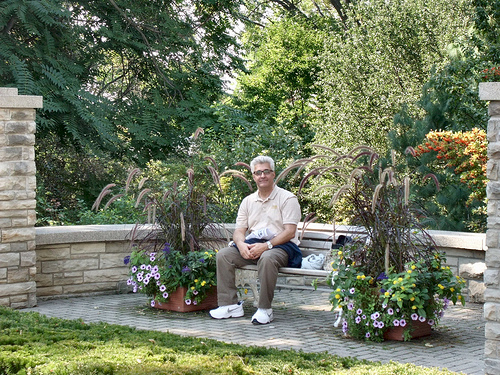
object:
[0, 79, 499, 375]
garden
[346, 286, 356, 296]
flower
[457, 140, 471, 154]
leaf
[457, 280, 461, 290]
leaf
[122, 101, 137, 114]
leaf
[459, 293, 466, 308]
leaf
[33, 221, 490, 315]
stone wall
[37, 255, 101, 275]
brick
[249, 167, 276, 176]
glasses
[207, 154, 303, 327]
man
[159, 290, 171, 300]
flowers